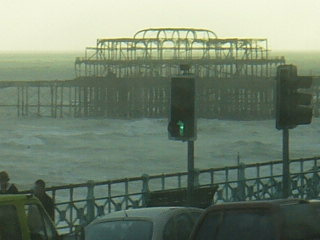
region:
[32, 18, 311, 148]
large and open structure in ocean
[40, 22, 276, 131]
framework for building erected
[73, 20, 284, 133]
different levels of building under construction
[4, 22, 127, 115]
building extension toward water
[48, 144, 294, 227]
metal railing over the ocean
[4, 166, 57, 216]
man between car and railing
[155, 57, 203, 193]
traffic light shining green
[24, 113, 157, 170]
low waves on surface of water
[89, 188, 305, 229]
hoods of different color cars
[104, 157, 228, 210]
bench in front of railing overlooking ocean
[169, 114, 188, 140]
glowing green on traffic light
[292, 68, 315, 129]
three covers on traffic light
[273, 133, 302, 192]
pole holding traffic light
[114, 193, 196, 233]
roof of car in traffic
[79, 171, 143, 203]
railing on street edge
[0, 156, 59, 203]
people walking on side of street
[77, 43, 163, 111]
frame of structure in water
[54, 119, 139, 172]
choppy water in front of structure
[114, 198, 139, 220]
antenna on car roof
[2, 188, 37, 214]
yellow roof of car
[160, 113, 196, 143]
The traffic light is green.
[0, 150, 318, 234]
A railing is behind the traffic lights.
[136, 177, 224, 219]
A bench is beneath the traffic light.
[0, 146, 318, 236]
The railing is made of metal.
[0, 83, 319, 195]
The ocean is visible.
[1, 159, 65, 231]
Two people stand next to the railing.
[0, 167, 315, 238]
Cars are parked next to the railing.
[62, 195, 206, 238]
The car is white.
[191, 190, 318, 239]
The car is red.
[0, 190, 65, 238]
The car is green.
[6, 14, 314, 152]
pier is in background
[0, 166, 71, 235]
two men near cars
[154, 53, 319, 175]
safety lights are on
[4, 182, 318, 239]
three cars near men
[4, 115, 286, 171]
sea is blue and grey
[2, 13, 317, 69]
sky is yellow and grey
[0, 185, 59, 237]
yellow car is near men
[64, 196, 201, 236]
grey car is near yellow car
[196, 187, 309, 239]
black car is near grey car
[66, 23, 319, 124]
construction is unfinished on pier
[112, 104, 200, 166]
Street light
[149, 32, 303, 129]
Intersection light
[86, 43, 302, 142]
Traffic lights along the roadway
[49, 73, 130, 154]
The ocean next to ta road way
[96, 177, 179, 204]
Railing along the water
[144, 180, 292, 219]
Bench overlooking the water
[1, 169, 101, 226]
People walking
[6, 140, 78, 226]
Pedestrians along the water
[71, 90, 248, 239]
Cars driving along the water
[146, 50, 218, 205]
Traffic light with a green light